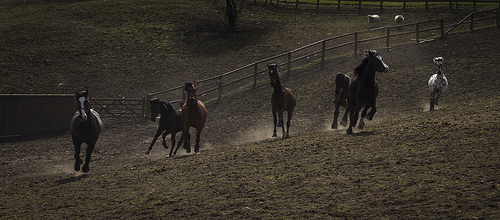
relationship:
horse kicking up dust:
[68, 88, 100, 177] [55, 159, 86, 176]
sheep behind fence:
[394, 11, 405, 25] [0, 6, 499, 131]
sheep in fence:
[394, 11, 405, 25] [0, 6, 499, 131]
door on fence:
[92, 95, 146, 119] [0, 6, 499, 131]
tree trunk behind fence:
[223, 1, 241, 26] [0, 6, 499, 131]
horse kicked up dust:
[68, 88, 100, 177] [55, 159, 86, 176]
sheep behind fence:
[367, 14, 384, 25] [0, 6, 499, 131]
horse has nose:
[68, 88, 100, 177] [77, 98, 93, 126]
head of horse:
[186, 82, 196, 110] [175, 79, 212, 151]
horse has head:
[68, 88, 100, 177] [71, 85, 96, 125]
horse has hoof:
[175, 79, 212, 151] [195, 148, 199, 154]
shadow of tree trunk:
[202, 21, 253, 58] [223, 1, 241, 26]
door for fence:
[92, 95, 146, 119] [0, 6, 499, 131]